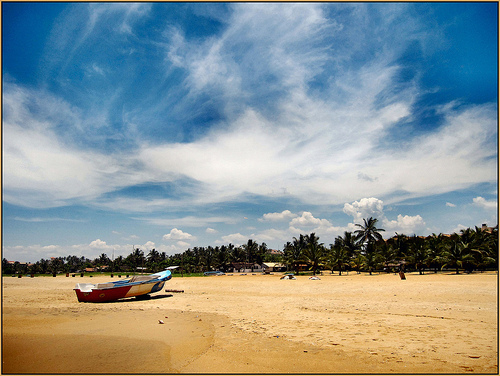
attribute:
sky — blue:
[2, 2, 498, 263]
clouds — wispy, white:
[1, 1, 499, 208]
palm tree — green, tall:
[348, 215, 389, 276]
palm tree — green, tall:
[334, 229, 362, 272]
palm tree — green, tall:
[299, 229, 326, 269]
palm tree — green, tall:
[241, 236, 260, 266]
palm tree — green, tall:
[132, 245, 145, 270]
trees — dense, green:
[1, 215, 499, 285]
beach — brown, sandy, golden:
[1, 270, 497, 375]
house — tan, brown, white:
[260, 257, 291, 271]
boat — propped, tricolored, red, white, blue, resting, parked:
[67, 266, 175, 305]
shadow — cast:
[111, 290, 176, 307]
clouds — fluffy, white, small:
[0, 192, 498, 261]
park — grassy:
[1, 260, 210, 280]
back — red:
[72, 273, 132, 306]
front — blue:
[151, 266, 176, 294]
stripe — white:
[125, 280, 155, 300]